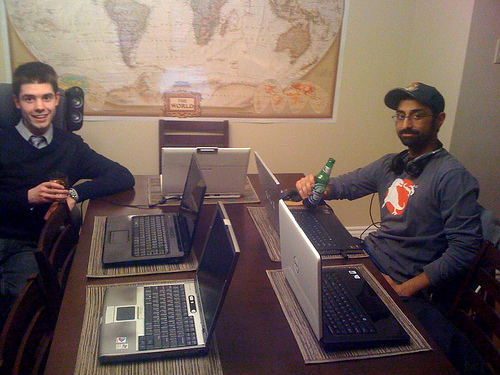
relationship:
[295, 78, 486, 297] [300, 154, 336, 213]
man holding beer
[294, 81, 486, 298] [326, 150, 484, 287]
person wearing shirt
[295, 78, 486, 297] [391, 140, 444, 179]
man has headphones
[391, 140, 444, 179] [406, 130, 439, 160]
headphones around neck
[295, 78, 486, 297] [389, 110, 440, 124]
man wearing eyeglasses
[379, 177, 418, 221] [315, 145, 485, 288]
dinosaur screenprinted on shirt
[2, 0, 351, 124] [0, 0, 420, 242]
map on wall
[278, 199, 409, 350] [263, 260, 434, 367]
laptop on placemat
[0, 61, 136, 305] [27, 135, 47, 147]
man wearing tie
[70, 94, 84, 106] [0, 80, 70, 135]
speaker attached to chair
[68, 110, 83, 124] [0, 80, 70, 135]
speaker attached to chair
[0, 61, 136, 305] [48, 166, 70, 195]
man holding glass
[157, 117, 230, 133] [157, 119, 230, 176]
tip of chair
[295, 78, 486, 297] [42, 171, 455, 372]
man at table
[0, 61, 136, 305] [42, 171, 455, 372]
man at table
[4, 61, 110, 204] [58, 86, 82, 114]
man sitting on a chair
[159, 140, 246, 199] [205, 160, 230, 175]
laptop has a lid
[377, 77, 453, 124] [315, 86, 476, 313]
cap on man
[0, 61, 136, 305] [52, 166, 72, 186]
man has drink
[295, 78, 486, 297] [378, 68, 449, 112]
man wearing cap